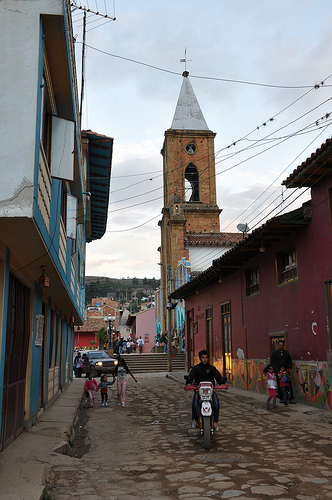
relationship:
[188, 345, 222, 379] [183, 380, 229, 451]
man on motorbike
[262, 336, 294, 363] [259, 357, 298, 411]
man and children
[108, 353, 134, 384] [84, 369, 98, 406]
woman and girls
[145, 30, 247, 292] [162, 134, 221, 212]
church with a bell tower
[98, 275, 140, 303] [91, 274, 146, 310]
trees on a hill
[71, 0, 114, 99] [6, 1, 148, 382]
antenna on building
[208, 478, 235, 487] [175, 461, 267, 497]
stone on ground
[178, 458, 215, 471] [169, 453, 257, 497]
stone on ground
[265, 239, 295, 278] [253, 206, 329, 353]
windows of a building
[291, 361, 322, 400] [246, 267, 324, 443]
mural on a wall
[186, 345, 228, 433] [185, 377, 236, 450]
man on a motorbike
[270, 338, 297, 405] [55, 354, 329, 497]
man walking on street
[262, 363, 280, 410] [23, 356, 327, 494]
children walking on street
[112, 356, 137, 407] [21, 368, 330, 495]
woman walking on street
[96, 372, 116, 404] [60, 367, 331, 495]
kids walking on street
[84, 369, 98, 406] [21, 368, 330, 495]
girls walking on street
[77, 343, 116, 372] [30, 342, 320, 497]
car on street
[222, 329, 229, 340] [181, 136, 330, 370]
window on building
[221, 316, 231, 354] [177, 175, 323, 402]
window on building